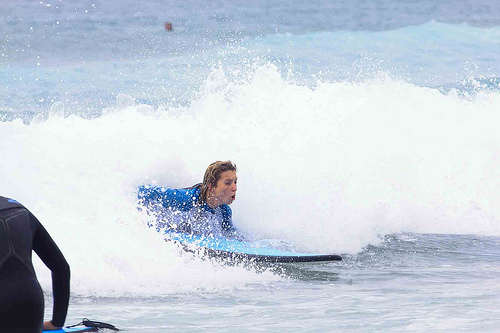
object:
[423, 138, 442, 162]
ground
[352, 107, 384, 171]
ground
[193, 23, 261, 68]
splashes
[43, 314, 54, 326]
hand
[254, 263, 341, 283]
shadow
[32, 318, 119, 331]
board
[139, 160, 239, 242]
person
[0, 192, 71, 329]
person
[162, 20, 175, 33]
person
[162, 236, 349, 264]
surf board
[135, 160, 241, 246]
surfer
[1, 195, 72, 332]
black suit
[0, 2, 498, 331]
ocean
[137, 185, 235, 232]
blue shirt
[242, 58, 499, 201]
spray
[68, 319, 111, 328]
rope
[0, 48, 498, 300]
wave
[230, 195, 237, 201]
mouth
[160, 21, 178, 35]
object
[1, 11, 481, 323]
water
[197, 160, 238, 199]
hair